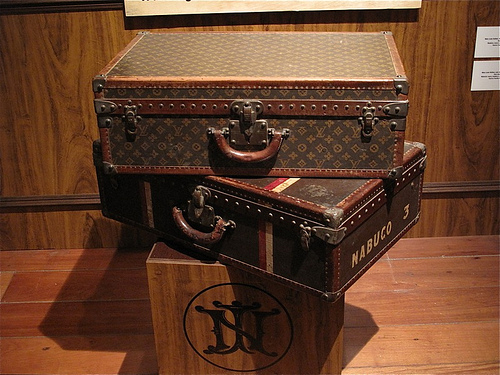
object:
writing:
[180, 282, 297, 371]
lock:
[226, 101, 268, 148]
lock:
[184, 186, 215, 232]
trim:
[113, 165, 394, 177]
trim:
[383, 32, 406, 77]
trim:
[105, 74, 397, 82]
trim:
[96, 33, 146, 73]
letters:
[351, 250, 360, 269]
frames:
[90, 32, 406, 90]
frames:
[313, 202, 345, 227]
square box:
[147, 240, 345, 375]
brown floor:
[0, 234, 500, 374]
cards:
[470, 59, 499, 91]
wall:
[1, 0, 500, 252]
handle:
[207, 127, 291, 164]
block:
[144, 240, 344, 373]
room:
[0, 0, 500, 374]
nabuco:
[351, 219, 393, 267]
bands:
[260, 217, 275, 274]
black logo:
[183, 283, 295, 372]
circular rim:
[183, 281, 294, 370]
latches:
[119, 102, 141, 136]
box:
[90, 31, 410, 178]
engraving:
[194, 287, 283, 356]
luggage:
[91, 139, 426, 303]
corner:
[309, 200, 355, 238]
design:
[91, 31, 411, 180]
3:
[402, 204, 413, 221]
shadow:
[37, 217, 157, 352]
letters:
[194, 300, 279, 356]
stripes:
[263, 221, 274, 274]